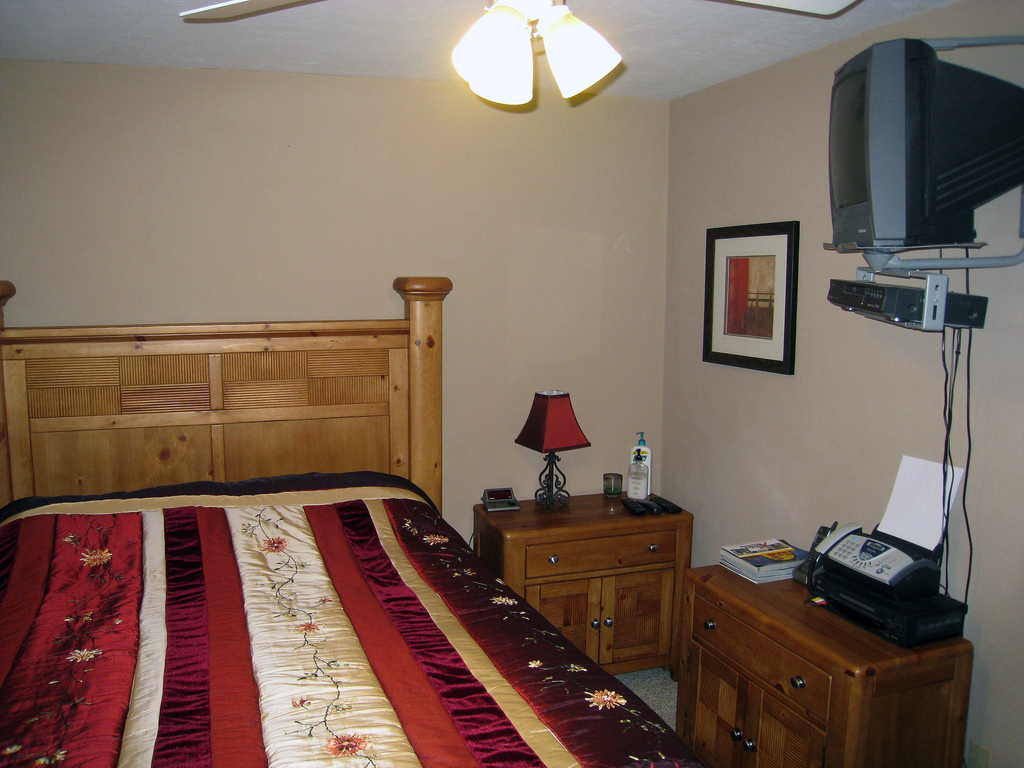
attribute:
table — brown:
[670, 550, 977, 766]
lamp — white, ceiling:
[485, 390, 591, 552]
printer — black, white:
[807, 525, 962, 644]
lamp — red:
[468, 361, 631, 535]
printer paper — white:
[874, 449, 969, 555]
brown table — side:
[476, 484, 695, 674]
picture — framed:
[698, 203, 861, 401]